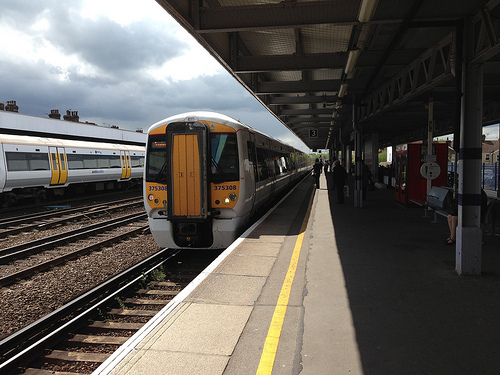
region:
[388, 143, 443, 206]
red vending machine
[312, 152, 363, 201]
people standing up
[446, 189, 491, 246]
woman sitting down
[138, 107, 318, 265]
yellow and white train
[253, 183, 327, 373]
thick yellow line on the ground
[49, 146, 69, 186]
white and yellow doors on the side of the train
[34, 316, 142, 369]
wooden planks on the train tracks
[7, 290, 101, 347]
two steel rods laying parallel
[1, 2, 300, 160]
cloudy, gray sky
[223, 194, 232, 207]
small light on the front of the train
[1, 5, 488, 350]
trains near a covered platform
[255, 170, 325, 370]
yellow line painted on the ground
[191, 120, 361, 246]
people standing near train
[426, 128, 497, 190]
buildings in the distance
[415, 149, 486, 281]
woman sitting behind a pillar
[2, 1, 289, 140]
clouds in the sky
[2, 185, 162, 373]
train tracks near each other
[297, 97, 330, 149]
telephone sign on roof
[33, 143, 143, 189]
doors on side of train are yellow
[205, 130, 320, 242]
shadow beside train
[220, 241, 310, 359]
the line is yellow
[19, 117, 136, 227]
the train is white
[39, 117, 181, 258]
the train is white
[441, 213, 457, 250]
The legs of the lady sitting on the bench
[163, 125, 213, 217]
The back door of the train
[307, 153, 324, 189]
A person standing on the yellow line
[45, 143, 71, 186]
Yellow door of the train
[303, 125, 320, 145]
Sign above the train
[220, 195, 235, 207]
A light on the back of the train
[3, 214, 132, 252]
The train tracks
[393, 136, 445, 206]
The ticket machine at the train station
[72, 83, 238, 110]
The clouds in the sky at the train station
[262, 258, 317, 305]
The yellow warning line at the train station